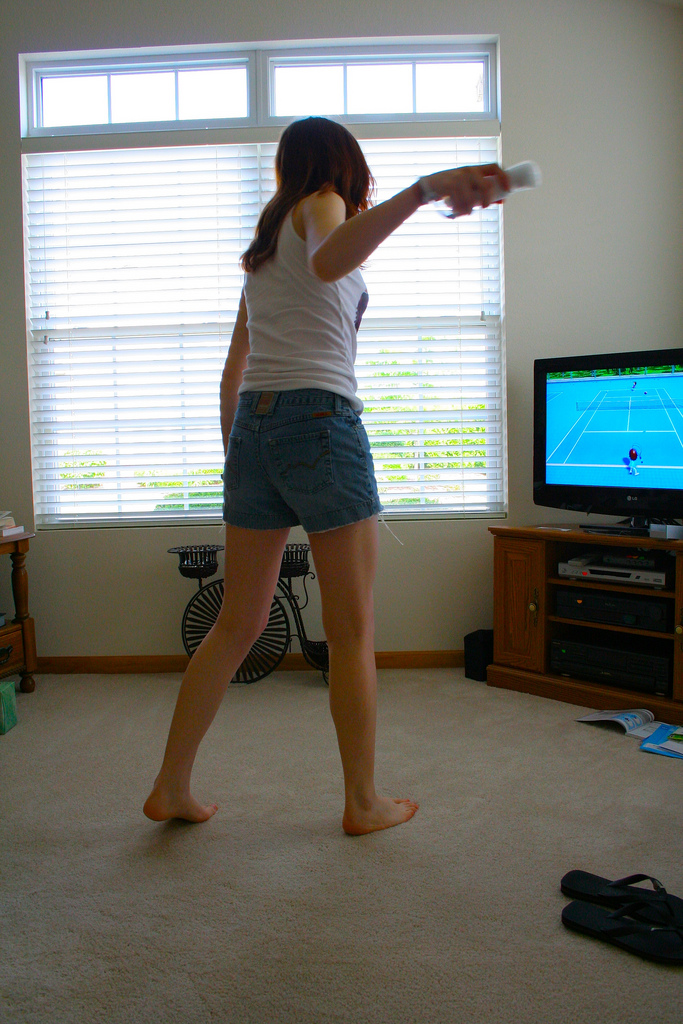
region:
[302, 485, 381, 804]
the leg of the girl playing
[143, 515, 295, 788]
the leg of the girl playing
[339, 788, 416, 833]
the foot of the girl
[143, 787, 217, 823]
the foot of the girl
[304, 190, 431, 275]
the arm of the woman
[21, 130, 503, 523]
the white plastic blinds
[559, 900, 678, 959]
the black flip flop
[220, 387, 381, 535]
the cut off jean shorts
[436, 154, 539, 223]
the white wii remote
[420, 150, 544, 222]
woman is holding a remote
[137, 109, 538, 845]
woman is playing wii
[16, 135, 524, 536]
blinds are color white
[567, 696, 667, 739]
book is on the floor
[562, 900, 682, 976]
flip flop is on the floor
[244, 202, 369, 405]
woman is wearing a white shirt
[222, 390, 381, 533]
woman is wearing blue shorts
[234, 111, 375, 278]
woman has long hair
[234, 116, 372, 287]
woman has brown hair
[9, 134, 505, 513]
white window blinds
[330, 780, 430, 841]
a girl's barefoot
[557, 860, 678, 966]
a pair of black flip flops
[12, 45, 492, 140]
a long window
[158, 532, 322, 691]
a black iron piece of furniture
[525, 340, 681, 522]
a black flat screen t.v.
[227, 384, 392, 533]
a woman's blue jean shorts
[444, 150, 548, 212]
a white game controller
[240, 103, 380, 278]
a woman's long hair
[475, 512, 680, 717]
a brown t.v. stand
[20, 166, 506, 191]
A blind for a window.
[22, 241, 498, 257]
A blind for a window.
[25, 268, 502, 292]
A blind for a window.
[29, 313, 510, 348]
A blind for a window.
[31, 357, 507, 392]
A blind for a window.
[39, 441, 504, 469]
A blind for a window.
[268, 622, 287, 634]
metal bar on decoration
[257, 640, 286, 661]
metal bar on decoration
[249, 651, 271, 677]
metal bar on decoration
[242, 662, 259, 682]
metal bar on decoration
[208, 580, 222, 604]
metal bar on decoration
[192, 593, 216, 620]
metal bar on decoration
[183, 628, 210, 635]
metal bar on decoration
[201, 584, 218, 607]
metal bar on decoration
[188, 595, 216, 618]
metal bar on decoration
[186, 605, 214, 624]
metal bar on decoration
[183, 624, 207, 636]
metal bar on decoration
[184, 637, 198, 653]
metal bar on decoration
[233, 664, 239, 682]
metal bar on decoration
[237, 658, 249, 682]
metal bar on decoration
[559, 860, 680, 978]
two black flip flops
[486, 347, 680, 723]
television on a wood stand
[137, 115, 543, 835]
person holding a wii controller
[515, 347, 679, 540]
tennis showing on television